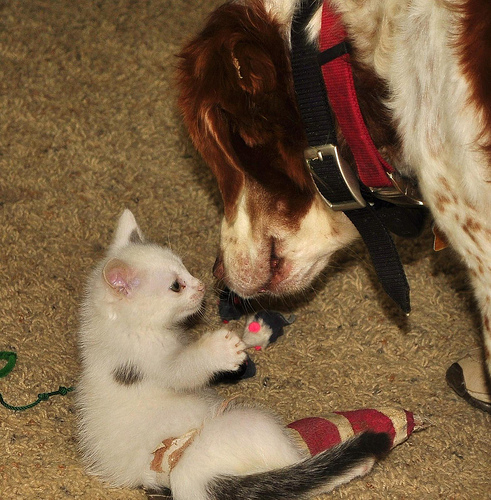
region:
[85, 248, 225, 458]
Small white kitten sitting on ground.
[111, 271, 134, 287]
Inside of cat's ear is pink.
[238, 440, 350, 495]
Cat has gray tail.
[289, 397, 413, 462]
Red and white cat toy near kitten.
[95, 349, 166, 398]
Kitten has gray spot on shoulder.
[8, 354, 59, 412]
Green string laying on ground.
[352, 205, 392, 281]
Dog has black collar.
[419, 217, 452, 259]
Gold tag on dogs collar.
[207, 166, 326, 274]
Dog has brown and white face.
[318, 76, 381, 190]
Dog has red collar on.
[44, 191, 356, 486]
the kitten is white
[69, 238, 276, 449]
the kitten is white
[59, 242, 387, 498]
A small black and white kitten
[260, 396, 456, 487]
A red and white toy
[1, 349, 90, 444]
A green string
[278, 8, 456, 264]
A black and red collar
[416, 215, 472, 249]
A brown dog tag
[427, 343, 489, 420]
A tip of a tennis shoe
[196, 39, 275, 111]
Something stuck in the dogs hair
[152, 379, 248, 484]
A string around the kitten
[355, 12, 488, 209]
White fur with brown spots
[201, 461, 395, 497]
The kittens black tail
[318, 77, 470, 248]
red dog collar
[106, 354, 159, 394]
black spot on white kitten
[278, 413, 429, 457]
red and white doggie toy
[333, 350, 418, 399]
tan shag carpet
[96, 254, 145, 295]
pink ear of white kitten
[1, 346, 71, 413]
green yarn for kitten to play with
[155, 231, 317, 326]
dog sniffing at kitten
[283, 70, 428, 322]
black dog collar with buckle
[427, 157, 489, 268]
brown spots on white dog fur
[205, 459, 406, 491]
grey tail on a kitten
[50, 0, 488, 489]
a dog and a cat are playing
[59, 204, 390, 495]
kitten is white with black spots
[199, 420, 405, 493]
tail of kitten is black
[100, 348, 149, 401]
a spot on body of white cat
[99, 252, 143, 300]
inside of cat ear is pink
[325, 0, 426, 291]
a red collar on neck of dog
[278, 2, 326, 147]
a black collar on neck of dog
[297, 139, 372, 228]
buckle of black collar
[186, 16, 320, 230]
ear of dog is brown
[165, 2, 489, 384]
dog is brown and white